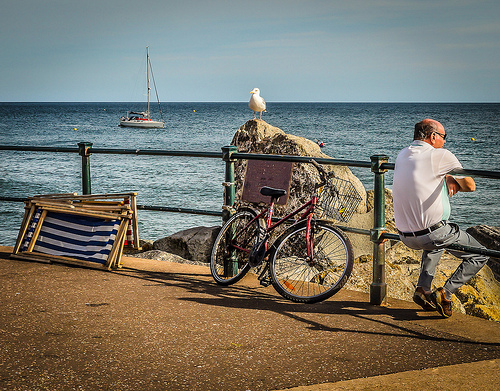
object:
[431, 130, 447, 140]
glasses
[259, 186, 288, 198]
seat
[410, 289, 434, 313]
shoe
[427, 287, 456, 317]
shoe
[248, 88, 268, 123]
bird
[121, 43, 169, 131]
boat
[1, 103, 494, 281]
ocean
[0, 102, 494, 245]
water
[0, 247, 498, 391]
ground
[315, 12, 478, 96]
sky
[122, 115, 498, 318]
rock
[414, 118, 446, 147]
head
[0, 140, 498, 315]
fence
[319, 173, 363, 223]
basket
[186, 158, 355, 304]
bicycle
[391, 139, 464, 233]
shirt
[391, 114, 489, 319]
man